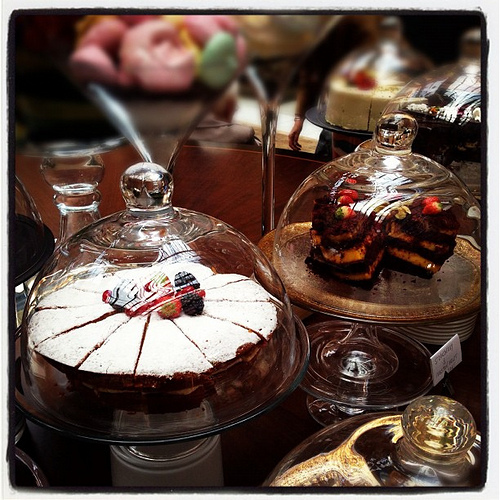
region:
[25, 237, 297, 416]
A cake on a cake platter.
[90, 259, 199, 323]
Fruit on the cake.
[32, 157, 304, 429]
A glass lid on the platter.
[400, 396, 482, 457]
A handle for the lid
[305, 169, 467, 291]
Chocolate cake under the lid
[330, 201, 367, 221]
Strawberry on the cake.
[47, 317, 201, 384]
The cake has white frosting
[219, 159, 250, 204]
A wooden table.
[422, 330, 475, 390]
A sign for the cake.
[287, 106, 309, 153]
The hand of a person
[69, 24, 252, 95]
this dessert is pink and green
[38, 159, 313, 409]
the dome lid is clear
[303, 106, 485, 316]
the lid is clear so you can see through it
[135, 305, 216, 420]
the cake is chocolate and white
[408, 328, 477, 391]
the tag is white and black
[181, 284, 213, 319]
the berry is black in color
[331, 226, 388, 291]
the cake is chocolate and camel in color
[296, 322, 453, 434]
the cake stand is glass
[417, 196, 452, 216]
the topping is red white and green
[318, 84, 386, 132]
the cake has white frosting on it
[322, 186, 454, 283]
Chocolate cake in glass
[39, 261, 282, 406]
Delicious looking cake under glass dome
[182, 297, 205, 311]
Blackberry on top of cake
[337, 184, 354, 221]
Strawberries on top of cake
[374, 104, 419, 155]
Glass knob on the dome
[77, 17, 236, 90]
Ice cream in glass cup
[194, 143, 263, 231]
Wooden table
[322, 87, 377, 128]
White cake under dome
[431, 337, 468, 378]
Handwritten note attached to glass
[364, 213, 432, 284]
Partially eaten cake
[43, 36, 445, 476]
Picture is taken in bakery.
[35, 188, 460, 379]
Cakes are under the dome cap.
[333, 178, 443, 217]
Cherries are red color.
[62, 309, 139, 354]
Cream is white color.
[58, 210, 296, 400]
Dome are made of glass.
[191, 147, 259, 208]
Table is brown color.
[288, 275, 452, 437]
Cake container is placed in table.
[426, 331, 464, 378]
Name boards are white color.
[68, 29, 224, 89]
Candies are pink and green color.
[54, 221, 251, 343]
Reflection is seen in glass.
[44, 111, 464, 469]
Glass containers with pastries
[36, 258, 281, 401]
White powdered cake with fruits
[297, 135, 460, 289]
Brown cake with filling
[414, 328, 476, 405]
White sign in front of the cases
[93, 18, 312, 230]
Tall clear glasses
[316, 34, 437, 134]
Beige pastry in a clear container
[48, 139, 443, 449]
The containers are on a wood counter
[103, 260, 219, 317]
Red raspberries and blue blueberries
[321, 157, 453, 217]
Strawberries on top of the cake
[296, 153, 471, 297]
The pastry has a slice missing